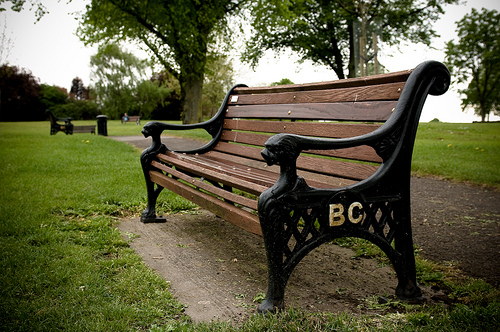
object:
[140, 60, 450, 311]
bench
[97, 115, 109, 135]
can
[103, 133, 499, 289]
path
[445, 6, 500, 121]
tree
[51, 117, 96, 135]
bench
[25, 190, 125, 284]
grass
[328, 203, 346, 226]
letters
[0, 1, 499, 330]
park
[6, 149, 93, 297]
field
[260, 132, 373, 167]
handles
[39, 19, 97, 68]
sky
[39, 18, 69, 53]
cloud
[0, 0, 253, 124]
trees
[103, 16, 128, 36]
leaves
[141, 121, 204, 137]
iron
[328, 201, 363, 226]
bc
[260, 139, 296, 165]
animal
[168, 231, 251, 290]
cement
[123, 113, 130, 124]
person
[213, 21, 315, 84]
middle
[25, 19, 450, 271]
scene